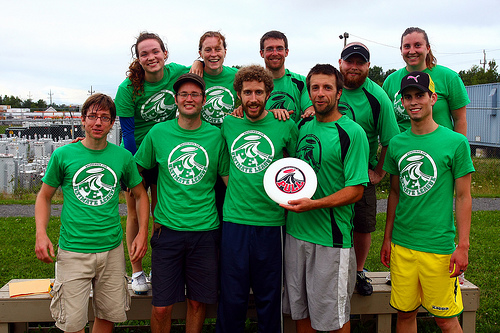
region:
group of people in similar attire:
[25, 20, 478, 332]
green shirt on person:
[385, 129, 470, 254]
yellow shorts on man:
[387, 245, 464, 317]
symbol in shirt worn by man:
[396, 149, 438, 197]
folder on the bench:
[8, 274, 50, 299]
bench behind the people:
[5, 270, 482, 326]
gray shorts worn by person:
[282, 240, 354, 330]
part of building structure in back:
[466, 81, 499, 143]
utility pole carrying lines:
[46, 87, 56, 103]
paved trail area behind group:
[0, 203, 34, 215]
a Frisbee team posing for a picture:
[7, 12, 491, 331]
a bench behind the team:
[0, 259, 484, 331]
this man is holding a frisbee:
[245, 63, 362, 248]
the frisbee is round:
[254, 146, 319, 210]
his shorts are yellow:
[385, 237, 475, 325]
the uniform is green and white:
[135, 117, 230, 230]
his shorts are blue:
[148, 217, 213, 327]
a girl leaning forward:
[105, 24, 200, 149]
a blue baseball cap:
[335, 37, 370, 64]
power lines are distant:
[35, 79, 110, 106]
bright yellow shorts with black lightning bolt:
[392, 241, 465, 317]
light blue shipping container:
[461, 79, 498, 148]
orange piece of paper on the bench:
[8, 278, 51, 297]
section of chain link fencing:
[1, 115, 125, 202]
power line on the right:
[339, 32, 496, 67]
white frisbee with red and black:
[263, 156, 317, 204]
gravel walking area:
[1, 195, 498, 212]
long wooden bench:
[1, 271, 478, 329]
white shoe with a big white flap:
[131, 270, 148, 293]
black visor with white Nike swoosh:
[340, 42, 370, 62]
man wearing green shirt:
[30, 101, 141, 321]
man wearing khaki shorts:
[23, 91, 146, 318]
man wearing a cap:
[376, 67, 483, 327]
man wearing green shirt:
[377, 68, 474, 328]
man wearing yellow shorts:
[386, 75, 461, 316]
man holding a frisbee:
[272, 61, 350, 331]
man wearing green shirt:
[282, 68, 373, 328]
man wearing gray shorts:
[285, 65, 361, 331]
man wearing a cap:
[143, 75, 210, 331]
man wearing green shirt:
[150, 71, 220, 330]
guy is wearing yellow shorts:
[392, 235, 483, 332]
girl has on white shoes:
[118, 254, 164, 303]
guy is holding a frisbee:
[263, 157, 340, 220]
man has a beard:
[242, 91, 267, 124]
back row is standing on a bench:
[117, 31, 478, 295]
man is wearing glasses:
[83, 110, 118, 128]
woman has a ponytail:
[114, 33, 175, 102]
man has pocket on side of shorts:
[38, 273, 74, 326]